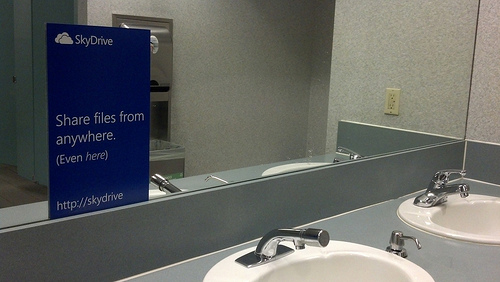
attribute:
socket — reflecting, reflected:
[382, 87, 403, 118]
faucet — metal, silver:
[233, 227, 331, 270]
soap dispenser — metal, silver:
[384, 230, 422, 257]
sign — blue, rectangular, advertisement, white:
[45, 21, 152, 219]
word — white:
[54, 112, 92, 130]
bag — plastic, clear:
[148, 136, 187, 160]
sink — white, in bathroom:
[202, 235, 434, 282]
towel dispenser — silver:
[116, 23, 174, 92]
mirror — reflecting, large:
[0, 0, 480, 230]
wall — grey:
[464, 1, 500, 141]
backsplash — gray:
[0, 140, 466, 282]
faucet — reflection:
[149, 172, 183, 195]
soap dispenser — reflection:
[201, 173, 231, 185]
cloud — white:
[53, 30, 75, 45]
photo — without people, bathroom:
[0, 0, 499, 281]